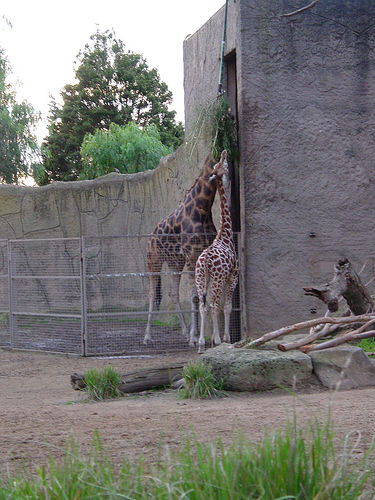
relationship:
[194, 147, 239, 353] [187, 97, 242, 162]
baby giraffe reaches for food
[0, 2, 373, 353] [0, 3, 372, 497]
building of zoo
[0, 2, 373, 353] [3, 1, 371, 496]
building of enclosure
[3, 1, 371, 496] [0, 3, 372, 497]
enclosure of zoo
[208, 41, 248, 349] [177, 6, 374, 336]
door of building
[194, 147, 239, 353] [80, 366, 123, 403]
baby giraffe eating grass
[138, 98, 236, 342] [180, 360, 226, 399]
giraffe eating grass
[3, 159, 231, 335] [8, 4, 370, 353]
wall of enclosure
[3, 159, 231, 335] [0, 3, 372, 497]
wall of zoo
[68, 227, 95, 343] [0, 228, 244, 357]
pole on fence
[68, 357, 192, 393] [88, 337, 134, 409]
log and grass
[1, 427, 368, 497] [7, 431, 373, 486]
patch of grass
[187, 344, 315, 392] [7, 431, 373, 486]
rock and grass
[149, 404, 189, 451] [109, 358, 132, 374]
part of ground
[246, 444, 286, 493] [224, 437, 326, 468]
part of grass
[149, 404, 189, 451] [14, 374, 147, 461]
part of ground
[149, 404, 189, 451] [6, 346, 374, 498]
part of ground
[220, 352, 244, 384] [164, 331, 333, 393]
part of stone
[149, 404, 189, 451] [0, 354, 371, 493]
part of ground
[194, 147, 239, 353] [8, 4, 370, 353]
baby giraffe on side of enclosure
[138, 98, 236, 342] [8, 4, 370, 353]
giraffe on side of enclosure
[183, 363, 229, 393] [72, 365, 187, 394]
grass near log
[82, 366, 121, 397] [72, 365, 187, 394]
grass near log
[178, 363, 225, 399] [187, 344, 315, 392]
grass near rock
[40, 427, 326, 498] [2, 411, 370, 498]
grass in foreground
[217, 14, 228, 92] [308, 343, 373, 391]
pole hangs along rock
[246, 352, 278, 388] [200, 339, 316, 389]
part of a stone